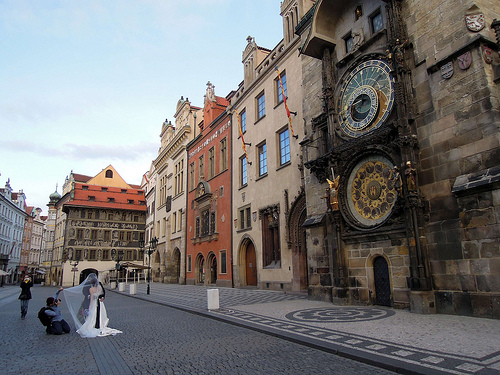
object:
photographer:
[34, 294, 73, 337]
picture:
[54, 298, 62, 306]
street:
[0, 277, 410, 375]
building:
[291, 0, 500, 314]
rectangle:
[204, 287, 222, 311]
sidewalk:
[114, 277, 500, 373]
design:
[274, 299, 402, 327]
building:
[186, 85, 230, 287]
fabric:
[91, 278, 107, 331]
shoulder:
[96, 281, 104, 290]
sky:
[0, 0, 291, 213]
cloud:
[1, 134, 159, 163]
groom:
[74, 271, 107, 330]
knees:
[58, 323, 73, 336]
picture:
[0, 0, 499, 375]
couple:
[70, 268, 110, 338]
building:
[132, 163, 159, 279]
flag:
[139, 171, 152, 189]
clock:
[330, 60, 402, 141]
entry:
[360, 248, 397, 311]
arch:
[361, 250, 392, 275]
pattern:
[225, 293, 500, 375]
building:
[57, 158, 149, 281]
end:
[11, 281, 115, 295]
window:
[365, 4, 388, 39]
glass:
[369, 12, 385, 33]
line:
[133, 293, 418, 375]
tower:
[294, 0, 440, 319]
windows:
[272, 67, 291, 109]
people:
[15, 271, 36, 321]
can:
[204, 286, 221, 312]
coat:
[17, 280, 36, 301]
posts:
[132, 268, 137, 284]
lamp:
[145, 234, 161, 296]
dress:
[77, 291, 121, 336]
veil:
[60, 272, 100, 332]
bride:
[73, 276, 115, 339]